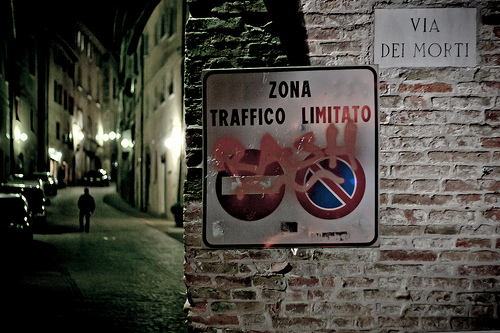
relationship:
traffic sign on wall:
[199, 61, 383, 253] [177, 1, 499, 332]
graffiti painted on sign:
[213, 118, 360, 200] [199, 61, 383, 253]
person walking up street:
[78, 184, 99, 235] [1, 181, 190, 332]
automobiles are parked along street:
[1, 168, 113, 248] [1, 181, 190, 332]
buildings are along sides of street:
[1, 1, 185, 220] [1, 181, 190, 332]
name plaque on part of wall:
[372, 4, 479, 72] [177, 1, 499, 332]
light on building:
[19, 130, 30, 144] [1, 1, 44, 177]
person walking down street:
[78, 184, 99, 235] [1, 181, 190, 332]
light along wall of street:
[19, 130, 30, 144] [1, 181, 190, 332]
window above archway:
[120, 136, 136, 152] [119, 144, 135, 206]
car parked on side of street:
[78, 166, 112, 188] [1, 181, 190, 332]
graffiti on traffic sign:
[213, 118, 360, 200] [199, 61, 383, 253]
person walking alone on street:
[78, 184, 99, 235] [1, 181, 190, 332]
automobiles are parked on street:
[1, 168, 113, 248] [1, 181, 190, 332]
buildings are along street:
[1, 1, 185, 220] [1, 181, 190, 332]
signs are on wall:
[198, 1, 482, 254] [177, 1, 499, 332]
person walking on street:
[78, 184, 99, 235] [1, 181, 190, 332]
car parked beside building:
[78, 166, 112, 188] [45, 1, 121, 181]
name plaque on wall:
[372, 4, 479, 72] [177, 1, 499, 332]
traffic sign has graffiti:
[199, 61, 383, 253] [213, 118, 360, 200]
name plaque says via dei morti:
[372, 4, 479, 72] [381, 16, 471, 61]